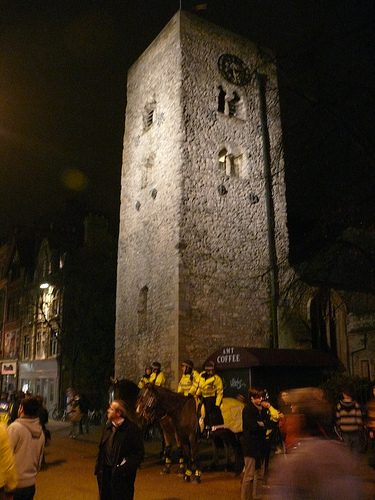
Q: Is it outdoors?
A: Yes, it is outdoors.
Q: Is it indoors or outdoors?
A: It is outdoors.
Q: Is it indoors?
A: No, it is outdoors.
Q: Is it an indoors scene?
A: No, it is outdoors.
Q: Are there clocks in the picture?
A: Yes, there is a clock.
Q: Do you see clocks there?
A: Yes, there is a clock.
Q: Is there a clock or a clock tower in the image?
A: Yes, there is a clock.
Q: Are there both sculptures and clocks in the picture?
A: No, there is a clock but no sculptures.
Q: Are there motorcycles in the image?
A: No, there are no motorcycles.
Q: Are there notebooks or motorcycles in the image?
A: No, there are no motorcycles or notebooks.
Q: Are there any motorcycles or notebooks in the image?
A: No, there are no motorcycles or notebooks.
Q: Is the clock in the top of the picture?
A: Yes, the clock is in the top of the image.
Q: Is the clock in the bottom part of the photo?
A: No, the clock is in the top of the image.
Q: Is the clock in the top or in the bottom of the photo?
A: The clock is in the top of the image.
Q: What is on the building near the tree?
A: The clock is on the tower.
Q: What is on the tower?
A: The clock is on the tower.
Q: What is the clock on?
A: The clock is on the tower.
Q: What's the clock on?
A: The clock is on the tower.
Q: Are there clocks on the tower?
A: Yes, there is a clock on the tower.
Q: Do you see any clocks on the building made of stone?
A: Yes, there is a clock on the tower.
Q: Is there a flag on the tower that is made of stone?
A: No, there is a clock on the tower.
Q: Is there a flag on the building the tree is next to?
A: No, there is a clock on the tower.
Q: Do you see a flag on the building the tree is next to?
A: No, there is a clock on the tower.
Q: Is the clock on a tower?
A: Yes, the clock is on a tower.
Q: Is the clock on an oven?
A: No, the clock is on a tower.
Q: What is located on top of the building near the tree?
A: The clock is on top of the tower.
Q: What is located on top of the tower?
A: The clock is on top of the tower.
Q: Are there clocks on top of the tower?
A: Yes, there is a clock on top of the tower.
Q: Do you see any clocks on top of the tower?
A: Yes, there is a clock on top of the tower.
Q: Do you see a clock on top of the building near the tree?
A: Yes, there is a clock on top of the tower.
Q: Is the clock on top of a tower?
A: Yes, the clock is on top of a tower.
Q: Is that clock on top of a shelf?
A: No, the clock is on top of a tower.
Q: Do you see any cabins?
A: No, there are no cabins.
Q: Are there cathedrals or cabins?
A: No, there are no cabins or cathedrals.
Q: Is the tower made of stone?
A: Yes, the tower is made of stone.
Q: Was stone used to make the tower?
A: Yes, the tower is made of stone.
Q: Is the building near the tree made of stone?
A: Yes, the tower is made of stone.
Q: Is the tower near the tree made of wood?
A: No, the tower is made of stone.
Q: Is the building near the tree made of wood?
A: No, the tower is made of stone.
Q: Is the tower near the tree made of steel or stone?
A: The tower is made of stone.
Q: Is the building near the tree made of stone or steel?
A: The tower is made of stone.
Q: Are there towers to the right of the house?
A: Yes, there is a tower to the right of the house.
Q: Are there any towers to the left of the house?
A: No, the tower is to the right of the house.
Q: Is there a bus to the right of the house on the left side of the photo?
A: No, there is a tower to the right of the house.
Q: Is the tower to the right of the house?
A: Yes, the tower is to the right of the house.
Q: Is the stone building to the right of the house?
A: Yes, the tower is to the right of the house.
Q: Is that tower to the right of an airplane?
A: No, the tower is to the right of the house.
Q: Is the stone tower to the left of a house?
A: No, the tower is to the right of a house.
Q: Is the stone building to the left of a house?
A: No, the tower is to the right of a house.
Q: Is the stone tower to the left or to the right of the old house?
A: The tower is to the right of the house.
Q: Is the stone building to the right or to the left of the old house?
A: The tower is to the right of the house.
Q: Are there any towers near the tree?
A: Yes, there is a tower near the tree.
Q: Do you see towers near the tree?
A: Yes, there is a tower near the tree.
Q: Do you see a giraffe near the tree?
A: No, there is a tower near the tree.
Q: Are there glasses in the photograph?
A: No, there are no glasses.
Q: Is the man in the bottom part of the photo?
A: Yes, the man is in the bottom of the image.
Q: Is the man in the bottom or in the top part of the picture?
A: The man is in the bottom of the image.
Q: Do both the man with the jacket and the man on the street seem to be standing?
A: Yes, both the man and the man are standing.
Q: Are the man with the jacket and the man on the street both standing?
A: Yes, both the man and the man are standing.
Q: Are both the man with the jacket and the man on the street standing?
A: Yes, both the man and the man are standing.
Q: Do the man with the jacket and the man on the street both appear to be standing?
A: Yes, both the man and the man are standing.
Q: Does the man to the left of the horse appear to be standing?
A: Yes, the man is standing.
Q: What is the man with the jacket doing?
A: The man is standing.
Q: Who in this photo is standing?
A: The man is standing.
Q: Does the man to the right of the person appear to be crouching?
A: No, the man is standing.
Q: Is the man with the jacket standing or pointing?
A: The man is standing.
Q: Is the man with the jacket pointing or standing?
A: The man is standing.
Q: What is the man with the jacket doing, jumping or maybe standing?
A: The man is standing.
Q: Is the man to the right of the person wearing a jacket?
A: Yes, the man is wearing a jacket.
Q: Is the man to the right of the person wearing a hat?
A: No, the man is wearing a jacket.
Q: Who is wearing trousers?
A: The man is wearing trousers.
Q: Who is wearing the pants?
A: The man is wearing trousers.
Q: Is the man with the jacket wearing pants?
A: Yes, the man is wearing pants.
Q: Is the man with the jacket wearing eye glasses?
A: No, the man is wearing pants.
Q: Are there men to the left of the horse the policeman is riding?
A: Yes, there is a man to the left of the horse.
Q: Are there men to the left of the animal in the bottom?
A: Yes, there is a man to the left of the horse.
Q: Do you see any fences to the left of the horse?
A: No, there is a man to the left of the horse.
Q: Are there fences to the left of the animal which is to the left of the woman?
A: No, there is a man to the left of the horse.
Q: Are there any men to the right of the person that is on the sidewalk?
A: Yes, there is a man to the right of the person.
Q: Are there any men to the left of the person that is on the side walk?
A: No, the man is to the right of the person.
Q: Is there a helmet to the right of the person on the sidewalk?
A: No, there is a man to the right of the person.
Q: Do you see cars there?
A: No, there are no cars.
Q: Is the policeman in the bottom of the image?
A: Yes, the policeman is in the bottom of the image.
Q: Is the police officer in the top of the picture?
A: No, the police officer is in the bottom of the image.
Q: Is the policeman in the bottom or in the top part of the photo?
A: The policeman is in the bottom of the image.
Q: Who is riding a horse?
A: The police officer is riding a horse.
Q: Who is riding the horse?
A: The police officer is riding a horse.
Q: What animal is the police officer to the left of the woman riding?
A: The police officer is riding a horse.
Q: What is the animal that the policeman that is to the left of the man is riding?
A: The animal is a horse.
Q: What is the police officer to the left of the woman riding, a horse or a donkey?
A: The policeman is riding a horse.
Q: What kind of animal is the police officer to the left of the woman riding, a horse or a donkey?
A: The policeman is riding a horse.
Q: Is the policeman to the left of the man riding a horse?
A: Yes, the policeman is riding a horse.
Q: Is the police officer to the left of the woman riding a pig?
A: No, the policeman is riding a horse.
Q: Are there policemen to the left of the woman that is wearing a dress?
A: Yes, there is a policeman to the left of the woman.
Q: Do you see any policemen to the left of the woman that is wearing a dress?
A: Yes, there is a policeman to the left of the woman.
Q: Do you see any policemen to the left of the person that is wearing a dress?
A: Yes, there is a policeman to the left of the woman.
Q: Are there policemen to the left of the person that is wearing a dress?
A: Yes, there is a policeman to the left of the woman.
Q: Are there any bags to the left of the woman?
A: No, there is a policeman to the left of the woman.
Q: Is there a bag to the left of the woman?
A: No, there is a policeman to the left of the woman.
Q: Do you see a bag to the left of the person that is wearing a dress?
A: No, there is a policeman to the left of the woman.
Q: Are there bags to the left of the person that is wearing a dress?
A: No, there is a policeman to the left of the woman.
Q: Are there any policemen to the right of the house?
A: Yes, there is a policeman to the right of the house.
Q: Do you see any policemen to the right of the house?
A: Yes, there is a policeman to the right of the house.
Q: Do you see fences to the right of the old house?
A: No, there is a policeman to the right of the house.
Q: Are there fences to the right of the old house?
A: No, there is a policeman to the right of the house.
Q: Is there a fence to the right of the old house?
A: No, there is a policeman to the right of the house.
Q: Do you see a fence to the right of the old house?
A: No, there is a policeman to the right of the house.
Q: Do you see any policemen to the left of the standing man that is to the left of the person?
A: Yes, there is a policeman to the left of the man.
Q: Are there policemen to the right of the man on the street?
A: No, the policeman is to the left of the man.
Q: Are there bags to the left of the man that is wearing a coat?
A: No, there is a policeman to the left of the man.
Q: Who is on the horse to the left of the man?
A: The policeman is on the horse.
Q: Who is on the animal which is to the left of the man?
A: The policeman is on the horse.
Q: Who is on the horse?
A: The policeman is on the horse.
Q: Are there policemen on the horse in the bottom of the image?
A: Yes, there is a policeman on the horse.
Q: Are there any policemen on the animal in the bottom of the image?
A: Yes, there is a policeman on the horse.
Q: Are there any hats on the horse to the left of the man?
A: No, there is a policeman on the horse.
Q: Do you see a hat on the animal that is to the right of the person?
A: No, there is a policeman on the horse.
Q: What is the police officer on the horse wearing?
A: The police officer is wearing a jacket.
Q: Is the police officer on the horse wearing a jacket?
A: Yes, the policeman is wearing a jacket.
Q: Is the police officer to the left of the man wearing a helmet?
A: No, the police officer is wearing a jacket.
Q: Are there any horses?
A: Yes, there is a horse.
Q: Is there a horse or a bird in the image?
A: Yes, there is a horse.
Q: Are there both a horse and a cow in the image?
A: No, there is a horse but no cows.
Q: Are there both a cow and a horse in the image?
A: No, there is a horse but no cows.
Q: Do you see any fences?
A: No, there are no fences.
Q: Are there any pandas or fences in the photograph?
A: No, there are no fences or pandas.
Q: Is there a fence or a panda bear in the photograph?
A: No, there are no fences or pandas.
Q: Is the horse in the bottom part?
A: Yes, the horse is in the bottom of the image.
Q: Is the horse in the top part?
A: No, the horse is in the bottom of the image.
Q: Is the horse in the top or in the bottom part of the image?
A: The horse is in the bottom of the image.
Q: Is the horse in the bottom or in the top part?
A: The horse is in the bottom of the image.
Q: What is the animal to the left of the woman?
A: The animal is a horse.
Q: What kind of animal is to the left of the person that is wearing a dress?
A: The animal is a horse.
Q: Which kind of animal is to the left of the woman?
A: The animal is a horse.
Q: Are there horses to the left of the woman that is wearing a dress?
A: Yes, there is a horse to the left of the woman.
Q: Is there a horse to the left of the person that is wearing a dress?
A: Yes, there is a horse to the left of the woman.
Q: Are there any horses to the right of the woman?
A: No, the horse is to the left of the woman.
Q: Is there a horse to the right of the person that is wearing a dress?
A: No, the horse is to the left of the woman.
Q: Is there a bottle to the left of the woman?
A: No, there is a horse to the left of the woman.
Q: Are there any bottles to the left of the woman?
A: No, there is a horse to the left of the woman.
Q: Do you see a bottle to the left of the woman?
A: No, there is a horse to the left of the woman.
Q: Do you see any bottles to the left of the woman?
A: No, there is a horse to the left of the woman.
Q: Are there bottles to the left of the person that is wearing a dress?
A: No, there is a horse to the left of the woman.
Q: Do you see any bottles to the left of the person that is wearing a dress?
A: No, there is a horse to the left of the woman.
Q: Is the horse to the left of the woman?
A: Yes, the horse is to the left of the woman.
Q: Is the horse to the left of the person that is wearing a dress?
A: Yes, the horse is to the left of the woman.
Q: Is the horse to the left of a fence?
A: No, the horse is to the left of the woman.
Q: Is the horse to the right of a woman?
A: No, the horse is to the left of a woman.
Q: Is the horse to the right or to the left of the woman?
A: The horse is to the left of the woman.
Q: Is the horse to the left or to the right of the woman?
A: The horse is to the left of the woman.